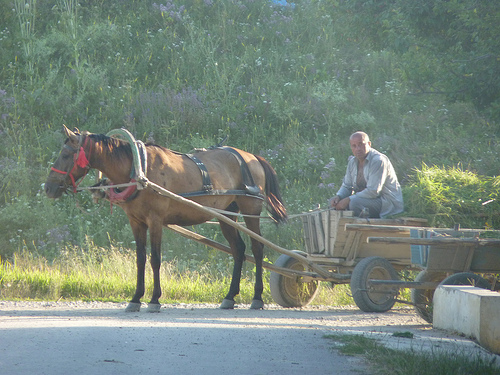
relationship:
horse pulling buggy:
[52, 140, 261, 316] [275, 212, 490, 302]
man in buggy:
[332, 130, 403, 217] [275, 212, 490, 302]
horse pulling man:
[52, 140, 261, 316] [332, 130, 403, 217]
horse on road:
[52, 140, 261, 316] [76, 306, 106, 328]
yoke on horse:
[124, 136, 151, 191] [52, 140, 261, 316]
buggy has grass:
[275, 212, 490, 302] [435, 181, 456, 199]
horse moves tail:
[52, 140, 261, 316] [271, 176, 279, 197]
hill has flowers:
[192, 26, 264, 50] [263, 88, 266, 99]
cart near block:
[416, 232, 490, 263] [445, 286, 483, 310]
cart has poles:
[416, 232, 490, 263] [366, 241, 483, 245]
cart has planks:
[416, 232, 490, 263] [419, 255, 424, 262]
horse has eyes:
[52, 140, 261, 316] [60, 153, 71, 161]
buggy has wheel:
[275, 212, 490, 302] [358, 263, 395, 309]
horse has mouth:
[52, 140, 261, 316] [51, 180, 62, 198]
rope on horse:
[252, 216, 259, 220] [52, 140, 261, 316]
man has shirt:
[332, 130, 403, 217] [365, 159, 379, 173]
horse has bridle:
[52, 140, 261, 316] [76, 151, 89, 169]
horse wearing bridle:
[52, 140, 261, 316] [76, 151, 89, 169]